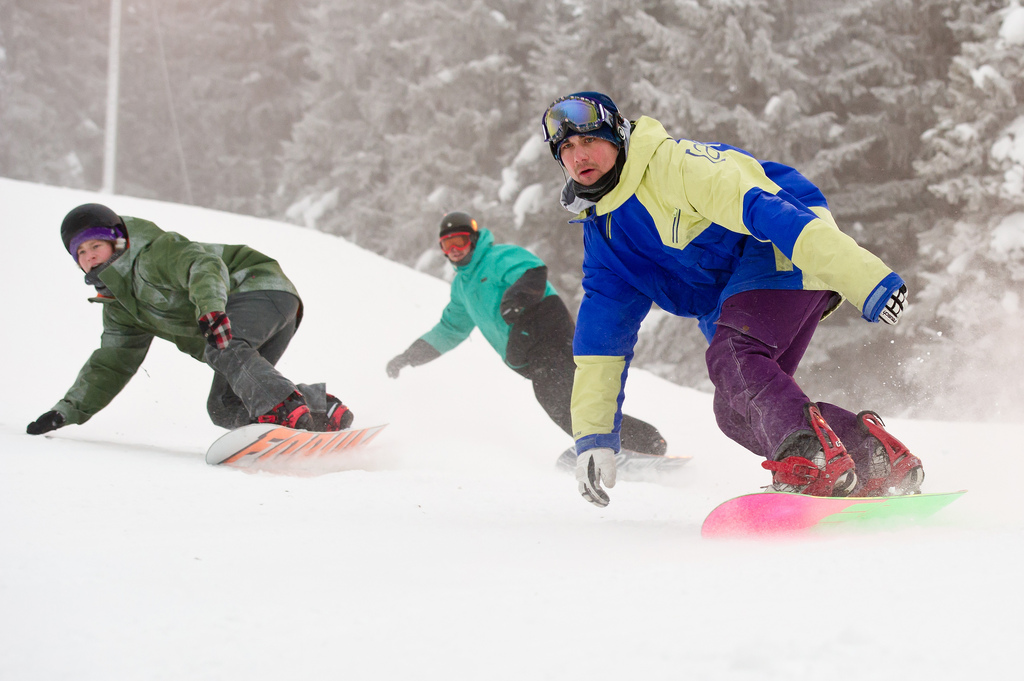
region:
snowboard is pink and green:
[681, 464, 969, 545]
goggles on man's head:
[531, 93, 621, 148]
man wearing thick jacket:
[532, 109, 915, 460]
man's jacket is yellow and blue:
[532, 102, 903, 476]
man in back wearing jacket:
[405, 233, 558, 379]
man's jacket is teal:
[409, 216, 562, 381]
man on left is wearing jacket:
[35, 198, 318, 436]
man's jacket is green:
[35, 195, 315, 437]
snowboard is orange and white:
[194, 412, 401, 480]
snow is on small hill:
[0, 166, 1022, 678]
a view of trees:
[196, 64, 390, 164]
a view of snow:
[209, 487, 383, 623]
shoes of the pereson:
[767, 430, 967, 533]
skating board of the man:
[226, 414, 375, 510]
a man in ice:
[47, 160, 308, 470]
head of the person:
[546, 94, 721, 197]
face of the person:
[407, 206, 491, 292]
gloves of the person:
[541, 435, 696, 525]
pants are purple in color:
[707, 266, 859, 486]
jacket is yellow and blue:
[577, 171, 878, 334]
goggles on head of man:
[555, 89, 633, 156]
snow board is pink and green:
[723, 449, 973, 536]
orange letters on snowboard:
[257, 425, 369, 468]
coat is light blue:
[445, 262, 575, 370]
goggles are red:
[437, 224, 482, 264]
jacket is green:
[91, 232, 291, 338]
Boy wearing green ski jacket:
[27, 200, 360, 426]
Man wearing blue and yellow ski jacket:
[543, 91, 924, 504]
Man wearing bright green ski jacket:
[385, 211, 668, 455]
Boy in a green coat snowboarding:
[27, 200, 389, 469]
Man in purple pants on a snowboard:
[537, 89, 964, 536]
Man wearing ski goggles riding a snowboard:
[385, 209, 690, 481]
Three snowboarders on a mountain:
[27, 92, 966, 538]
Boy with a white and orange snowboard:
[27, 202, 391, 466]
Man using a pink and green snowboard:
[540, 89, 965, 539]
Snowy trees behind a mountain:
[0, 0, 1019, 422]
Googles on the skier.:
[540, 101, 621, 136]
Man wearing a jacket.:
[537, 88, 929, 506]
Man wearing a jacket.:
[387, 215, 669, 454]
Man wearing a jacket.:
[27, 200, 354, 436]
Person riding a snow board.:
[704, 491, 957, 534]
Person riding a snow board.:
[204, 423, 372, 463]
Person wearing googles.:
[438, 232, 478, 252]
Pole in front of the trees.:
[104, 1, 120, 194]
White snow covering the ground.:
[1, 175, 1022, 675]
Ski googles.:
[530, 90, 623, 144]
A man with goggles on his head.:
[514, 92, 948, 565]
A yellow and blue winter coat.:
[517, 115, 910, 410]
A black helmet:
[428, 209, 489, 244]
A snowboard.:
[703, 386, 956, 555]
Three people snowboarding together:
[36, 66, 956, 607]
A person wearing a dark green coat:
[38, 188, 430, 479]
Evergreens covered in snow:
[5, 10, 1018, 423]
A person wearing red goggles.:
[387, 200, 669, 494]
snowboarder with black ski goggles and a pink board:
[543, 91, 629, 183]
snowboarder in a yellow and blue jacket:
[544, 91, 925, 506]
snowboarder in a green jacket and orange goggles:
[385, 209, 569, 402]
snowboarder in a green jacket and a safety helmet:
[386, 209, 570, 369]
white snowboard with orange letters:
[204, 414, 397, 473]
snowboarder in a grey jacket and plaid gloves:
[29, 200, 350, 431]